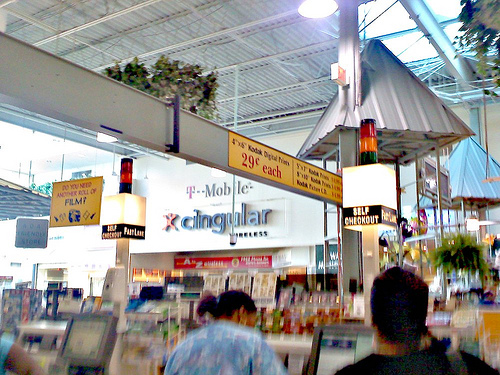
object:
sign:
[226, 129, 343, 205]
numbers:
[241, 152, 248, 169]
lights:
[359, 118, 377, 139]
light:
[96, 132, 119, 144]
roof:
[293, 37, 477, 167]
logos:
[186, 180, 253, 200]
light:
[297, 0, 338, 20]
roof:
[0, 0, 500, 162]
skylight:
[356, 0, 500, 65]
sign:
[174, 255, 273, 270]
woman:
[162, 285, 290, 374]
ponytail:
[196, 289, 218, 317]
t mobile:
[186, 180, 249, 201]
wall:
[0, 102, 499, 310]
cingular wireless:
[180, 202, 273, 239]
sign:
[49, 175, 104, 228]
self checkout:
[345, 206, 380, 226]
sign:
[342, 205, 382, 226]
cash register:
[54, 313, 119, 375]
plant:
[430, 228, 494, 282]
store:
[375, 157, 499, 374]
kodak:
[247, 143, 264, 156]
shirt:
[162, 318, 291, 373]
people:
[328, 263, 499, 373]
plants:
[96, 54, 225, 126]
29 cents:
[241, 152, 261, 170]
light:
[342, 163, 398, 212]